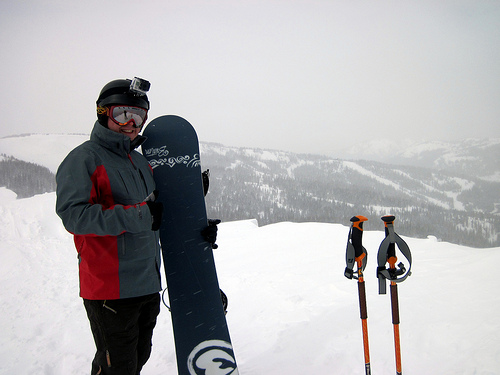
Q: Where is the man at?
A: Ski resort.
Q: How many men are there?
A: One.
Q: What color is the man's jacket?
A: Grey.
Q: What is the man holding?
A: Snowboard.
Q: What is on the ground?
A: Snow.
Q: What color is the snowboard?
A: Black.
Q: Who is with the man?
A: No one.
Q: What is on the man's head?
A: Hat.